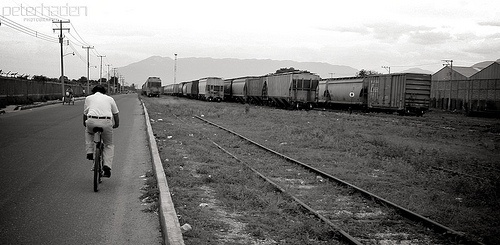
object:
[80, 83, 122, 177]
man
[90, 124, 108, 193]
bicycle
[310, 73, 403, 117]
train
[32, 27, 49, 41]
lines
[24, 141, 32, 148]
road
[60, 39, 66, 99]
pole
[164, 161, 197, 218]
grass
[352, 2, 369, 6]
clouds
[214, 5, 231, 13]
sky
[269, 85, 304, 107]
engine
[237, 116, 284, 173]
rail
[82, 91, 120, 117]
shirt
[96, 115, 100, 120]
belt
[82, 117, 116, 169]
pants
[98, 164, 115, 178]
shoes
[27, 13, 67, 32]
wires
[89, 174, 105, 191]
tire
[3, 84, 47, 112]
fence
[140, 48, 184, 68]
mountain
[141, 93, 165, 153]
curb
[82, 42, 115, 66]
lights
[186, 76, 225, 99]
car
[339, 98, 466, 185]
litter